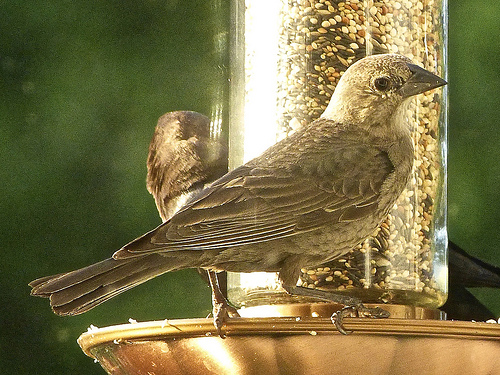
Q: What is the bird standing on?
A: Feeder.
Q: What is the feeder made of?
A: Glass.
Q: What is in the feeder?
A: Bird seed.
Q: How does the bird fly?
A: Wings.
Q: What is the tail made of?
A: Feathers.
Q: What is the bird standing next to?
A: Seeds.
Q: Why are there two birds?
A: To eat.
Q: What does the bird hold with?
A: Claws.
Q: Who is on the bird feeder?
A: Two brown birds.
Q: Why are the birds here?
A: To eat.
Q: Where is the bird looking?
A: At the camera.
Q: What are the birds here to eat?
A: Grains and seeds.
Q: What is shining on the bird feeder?
A: Sunlight.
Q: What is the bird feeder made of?
A: Plastic.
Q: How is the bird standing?
A: Hanging on to the lip of the feeder.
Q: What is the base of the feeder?
A: Copper.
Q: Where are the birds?
A: A bird feeder.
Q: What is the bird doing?
A: Getting food.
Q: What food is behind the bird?
A: Seeds.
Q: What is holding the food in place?
A: A glass container.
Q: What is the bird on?
A: The rim of the feeder.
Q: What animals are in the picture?
A: Birds.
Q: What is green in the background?
A: Trees.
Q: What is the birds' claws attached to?
A: The bottom of the feeding pan.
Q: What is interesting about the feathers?
A: The layers.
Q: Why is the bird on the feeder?
A: He is hungry.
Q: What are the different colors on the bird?
A: Beige, brown.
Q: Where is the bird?
A: On the feeder.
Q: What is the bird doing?
A: Watching.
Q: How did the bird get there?
A: He flew.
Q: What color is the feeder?
A: Copper.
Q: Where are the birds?
A: On the bird feeder.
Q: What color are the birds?
A: Brown.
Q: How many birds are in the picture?
A: Two.